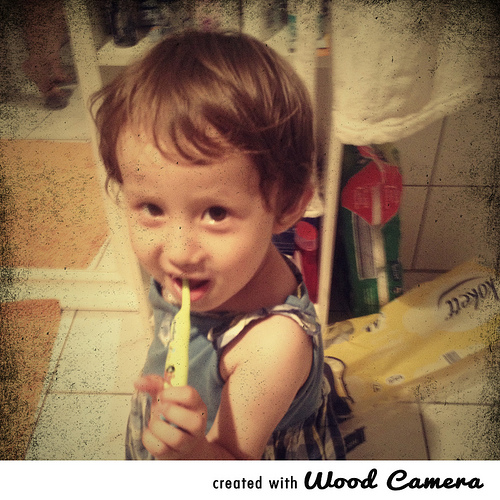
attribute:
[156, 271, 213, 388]
toothbrush — yellow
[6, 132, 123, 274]
rug — small, orange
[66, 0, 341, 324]
plastic shelf — white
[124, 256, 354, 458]
dress — white, blue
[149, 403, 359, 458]
dress — white, blue, checkered pattern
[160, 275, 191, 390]
brush — yellow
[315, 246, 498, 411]
bag — yellow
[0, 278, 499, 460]
floor — yellow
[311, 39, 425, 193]
towel — white